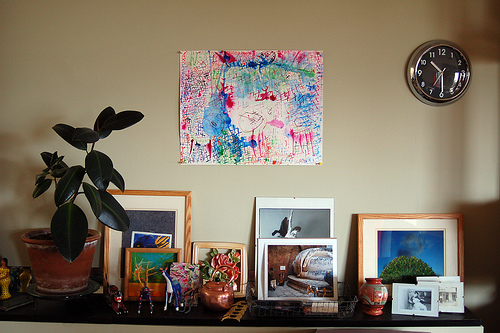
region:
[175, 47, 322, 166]
a child's drawing on wall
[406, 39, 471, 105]
a chrome and black wall clock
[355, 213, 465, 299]
a wood framed photograph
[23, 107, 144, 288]
a potted green plant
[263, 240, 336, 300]
a large photograph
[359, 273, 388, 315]
a small red and green vase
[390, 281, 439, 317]
framed black and white photograph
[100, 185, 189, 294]
a wood framed photograph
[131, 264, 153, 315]
a small giraffe toy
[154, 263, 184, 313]
a small giraffe toy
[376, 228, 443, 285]
a blue photo of the top of a green tree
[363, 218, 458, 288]
the white cardstock matting for that blue photo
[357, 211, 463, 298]
the little wooden frame that encloses all of the above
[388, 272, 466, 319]
several vintage black+white, grey+white, possibly sepiatone photos, long+thin, in lower right corner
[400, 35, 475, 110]
an industrial/school type clock telling us it's 10:29+~35 seconds- a.m. from sun's reflection,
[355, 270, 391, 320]
little green+rust brown vase-jar thing, southwest style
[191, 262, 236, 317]
a copper tea- or neti-pot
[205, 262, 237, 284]
handle+lid of copper pot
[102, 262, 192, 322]
three handmade animals, @ least one south or central american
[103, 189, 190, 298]
striped wooden frame holding photo that looks like tv static [at least all we can see of it does]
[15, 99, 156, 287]
THIS IS A PLANT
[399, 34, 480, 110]
THIS IS A CLOCK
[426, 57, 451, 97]
THE CLOCK HAS WHITE HANDS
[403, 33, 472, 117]
THE CLOCK HAS A BLACK FACE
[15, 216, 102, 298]
THE PLANT IS IN A TERRACOTTA VASE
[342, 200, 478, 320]
THE FRAME IS WOODEN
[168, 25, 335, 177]
THE PICTURE IS ON THE WALL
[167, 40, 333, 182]
THE PICTURE WAS DRAWN BY A CHILD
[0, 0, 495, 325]
THE WALL IS BEIGE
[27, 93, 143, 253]
THE LEAVES ON THE PLANT ARE BIG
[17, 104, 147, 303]
plant in a clay pot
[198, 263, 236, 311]
decorative brass tea kettle with handle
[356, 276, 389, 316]
small urn on a table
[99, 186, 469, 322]
pictures in frames on a table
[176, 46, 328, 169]
colorful painting on wall attached with pushpins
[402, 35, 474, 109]
round, silver rimmed clock on wall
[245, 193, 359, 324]
silver wire basket with prints inside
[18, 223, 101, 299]
clear glass dish under a clay pot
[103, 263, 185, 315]
animal figurines on a table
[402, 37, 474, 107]
white numerals and hands on a round clock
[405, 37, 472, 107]
Silver and black clock.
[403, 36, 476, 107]
Round clock hanging on the wall.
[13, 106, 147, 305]
Leafy green plant in pot.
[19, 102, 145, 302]
Plant with large leaves in brown por.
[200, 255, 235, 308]
Copper mini tea kettle.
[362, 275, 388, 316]
Mini brown vase with designs.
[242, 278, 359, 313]
Grey square wire container.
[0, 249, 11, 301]
Figurine of woman in yellow dress.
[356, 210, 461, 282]
Picture of top of green bush.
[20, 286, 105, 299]
Glass plate under potted plant.